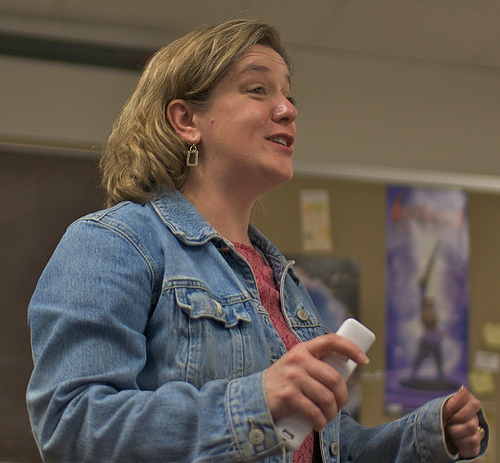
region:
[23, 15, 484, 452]
woman in denim jacket over red shirt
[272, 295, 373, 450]
hand holding white remote control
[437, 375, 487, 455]
curved fingers inside sleeve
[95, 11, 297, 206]
blonde hair to side and curled under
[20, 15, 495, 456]
woman in room with tan corkboard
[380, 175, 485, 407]
blue poster of figure with sword overhead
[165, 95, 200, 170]
rectangular gold dangling earring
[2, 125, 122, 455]
dark doorway behind woman's back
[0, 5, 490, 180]
white wall and ceiling with dark panel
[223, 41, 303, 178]
smiling face while talking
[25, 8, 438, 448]
Woman wearing blue jean jacket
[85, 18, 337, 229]
Woman with blonde hair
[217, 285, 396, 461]
Holding remote in hand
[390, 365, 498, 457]
Wearing ring on finger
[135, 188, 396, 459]
Wearing red printed shirt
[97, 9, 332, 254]
Woman wearing gold earrings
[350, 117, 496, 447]
Purple and white poster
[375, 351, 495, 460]
Hand is in fist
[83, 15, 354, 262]
Hair tucked behind ear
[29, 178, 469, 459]
Blue jean jacked has pocket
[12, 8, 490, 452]
This is a woman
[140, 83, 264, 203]
woman is wearing an earring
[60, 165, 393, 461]
the jacket is blue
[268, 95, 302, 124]
nose of a woman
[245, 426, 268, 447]
button on a jean jacket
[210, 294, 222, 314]
button on a jean jacket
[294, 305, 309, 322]
button on a jean jacket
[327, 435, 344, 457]
button on a jean jacket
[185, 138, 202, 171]
small earring of gold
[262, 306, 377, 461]
white video game remote control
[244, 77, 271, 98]
eye of a woman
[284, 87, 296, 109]
eye of a woman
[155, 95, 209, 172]
ear with an earring on it